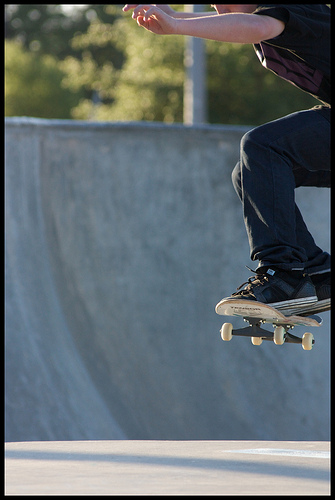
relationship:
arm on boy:
[128, 5, 288, 43] [120, 0, 335, 316]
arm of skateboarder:
[121, 5, 285, 44] [210, 3, 333, 315]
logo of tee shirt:
[254, 34, 322, 94] [251, 2, 334, 109]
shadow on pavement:
[7, 444, 327, 486] [8, 441, 333, 492]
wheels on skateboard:
[215, 318, 321, 356] [211, 289, 319, 327]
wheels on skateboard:
[215, 319, 315, 358] [201, 286, 334, 348]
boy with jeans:
[120, 0, 335, 316] [223, 104, 331, 266]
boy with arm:
[120, 0, 335, 316] [119, 2, 285, 43]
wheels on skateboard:
[273, 326, 286, 345] [216, 295, 322, 350]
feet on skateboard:
[207, 247, 333, 314] [208, 290, 327, 351]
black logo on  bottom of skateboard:
[226, 302, 261, 315] [216, 296, 333, 352]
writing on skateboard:
[229, 303, 262, 313] [216, 295, 322, 350]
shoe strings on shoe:
[230, 256, 272, 300] [209, 259, 333, 326]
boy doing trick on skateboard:
[120, 0, 335, 316] [208, 290, 327, 351]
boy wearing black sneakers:
[120, 0, 335, 316] [211, 264, 332, 353]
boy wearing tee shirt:
[120, 0, 335, 316] [255, 7, 329, 105]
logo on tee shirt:
[260, 33, 321, 92] [256, 3, 333, 119]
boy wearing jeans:
[120, 0, 335, 316] [224, 94, 325, 294]